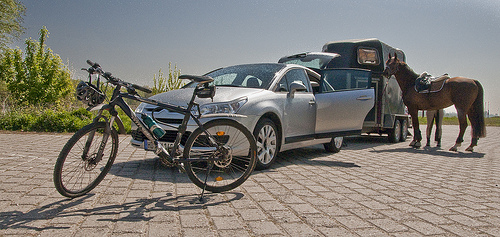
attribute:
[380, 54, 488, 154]
horse — brown, saddled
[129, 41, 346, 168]
car — silver, parked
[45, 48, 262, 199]
bicycle — black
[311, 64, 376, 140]
door — open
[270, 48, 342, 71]
trunk — open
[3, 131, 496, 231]
pavement — brick